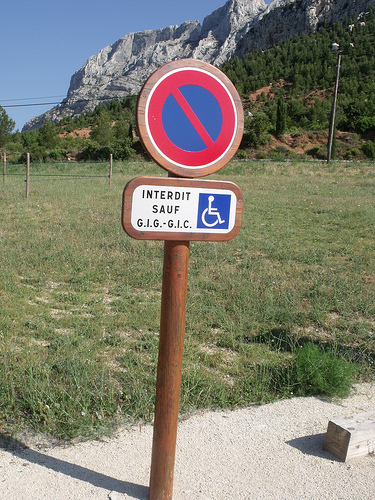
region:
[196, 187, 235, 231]
the square handicap symbol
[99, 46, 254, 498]
A sign on a wooden pole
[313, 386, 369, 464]
a railroad tie laying on the ground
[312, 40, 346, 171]
a telephone pole in the distance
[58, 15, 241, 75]
the grey rocky top of the mountain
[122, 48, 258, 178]
the round part of the sign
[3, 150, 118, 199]
part of a wooden fence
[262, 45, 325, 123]
green trees at the bottom of the mountain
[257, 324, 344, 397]
green grassy plants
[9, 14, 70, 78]
the clear blue sky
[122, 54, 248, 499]
a colorful sign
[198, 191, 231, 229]
a handicap symbol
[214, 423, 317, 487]
a sandy area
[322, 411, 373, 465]
a wooden block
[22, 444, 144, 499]
a shadow cast on the ground by a pole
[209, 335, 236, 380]
empty patches in the grass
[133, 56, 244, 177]
a circle with a diagonal line going through it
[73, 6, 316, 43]
a mountainous area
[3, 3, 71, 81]
a clear blue sky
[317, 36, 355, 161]
a tall lamppost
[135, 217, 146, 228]
a black letter 'G'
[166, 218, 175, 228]
a black letter 'G'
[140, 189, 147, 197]
a black letter 'I'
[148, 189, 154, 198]
a black letter 'N'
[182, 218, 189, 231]
a black letter 'C'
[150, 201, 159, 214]
a black letter 'S'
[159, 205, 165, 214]
a black letter 'A'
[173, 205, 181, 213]
a black letter 'F'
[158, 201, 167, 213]
a black letter 'A'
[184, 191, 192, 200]
a black letter 'T'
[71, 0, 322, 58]
Steep and jagged gray mountains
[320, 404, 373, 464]
Section of four by four lumber laying on the gravel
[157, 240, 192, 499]
Rusty steel pole for signs and notices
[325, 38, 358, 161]
Tall pole with two lights that turn on at night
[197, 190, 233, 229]
Handicapped access available sign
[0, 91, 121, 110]
Power and telephone lines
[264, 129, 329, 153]
Area with orange-like soil and no vegetation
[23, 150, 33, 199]
Wood fence post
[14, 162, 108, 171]
Area with patches of green grass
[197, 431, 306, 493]
Almost white colored gravel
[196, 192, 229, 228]
Handicapped symbol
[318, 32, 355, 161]
slightly leaning light pole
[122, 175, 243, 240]
Handicapped parking spot reference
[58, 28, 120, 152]
White cliffs backed by blue skies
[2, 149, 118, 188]
partial fence with wooden poles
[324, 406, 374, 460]
wooden block in gravel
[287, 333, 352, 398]
bushy green plant on side of parking area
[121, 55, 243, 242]
handicapped parking only sign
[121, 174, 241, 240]
parking for disabled veterans and handicapped people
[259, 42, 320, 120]
Bushy green trees